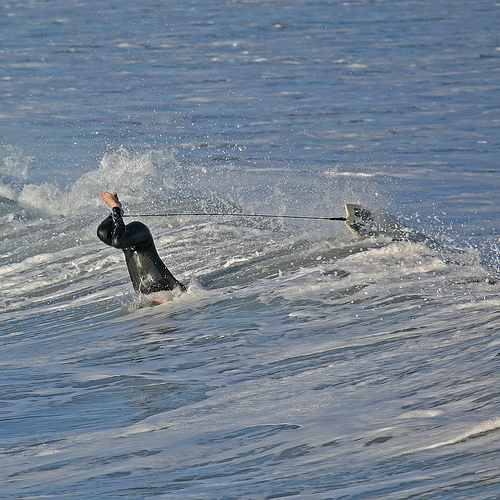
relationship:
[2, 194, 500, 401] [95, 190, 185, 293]
wave next to a person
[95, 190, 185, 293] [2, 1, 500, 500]
person in water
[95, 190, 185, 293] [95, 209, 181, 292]
person has on a wetsuit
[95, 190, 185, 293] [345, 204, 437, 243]
person has a surfboard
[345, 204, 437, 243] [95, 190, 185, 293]
surfboard attached to a person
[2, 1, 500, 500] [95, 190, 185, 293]
water has a person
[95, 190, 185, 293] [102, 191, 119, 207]
person has a foot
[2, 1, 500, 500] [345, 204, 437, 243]
water has a surfboard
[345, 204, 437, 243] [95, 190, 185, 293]
surfboard behind person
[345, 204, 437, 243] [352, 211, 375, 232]
surfboard has a design